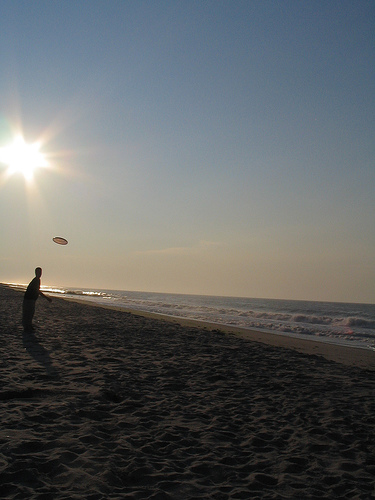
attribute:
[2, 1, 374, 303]
sky — clear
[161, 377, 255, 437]
sand — brown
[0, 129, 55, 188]
sun — yellow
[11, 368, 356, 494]
sand — beige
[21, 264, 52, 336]
person — looking up